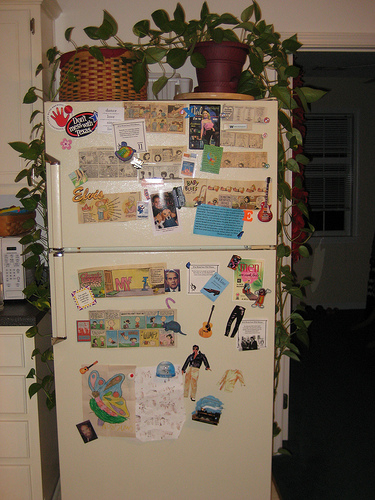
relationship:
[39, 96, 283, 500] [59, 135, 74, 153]
refrigerator covered with magnet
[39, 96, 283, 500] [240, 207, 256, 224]
refrigerator covered with magnet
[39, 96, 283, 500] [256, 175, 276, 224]
refrigerator covered with magnet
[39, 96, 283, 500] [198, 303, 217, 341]
refrigerator covered with magnet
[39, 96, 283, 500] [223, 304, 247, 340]
refrigerator covered with magnet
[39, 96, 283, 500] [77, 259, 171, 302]
refrigerator covered with comics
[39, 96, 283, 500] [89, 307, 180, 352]
refrigerator covered with comics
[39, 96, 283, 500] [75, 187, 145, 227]
refrigerator covered with comics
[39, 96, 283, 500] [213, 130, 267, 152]
refrigerator covered with comics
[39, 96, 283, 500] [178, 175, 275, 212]
refrigerator covered with comics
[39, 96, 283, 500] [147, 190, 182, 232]
refrigerator covered with photo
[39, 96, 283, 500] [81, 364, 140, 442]
refrigerator covered with artwork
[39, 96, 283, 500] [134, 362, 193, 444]
refrigerator covered with artwork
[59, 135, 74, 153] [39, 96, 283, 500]
magnet on refrigerator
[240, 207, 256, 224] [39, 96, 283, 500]
magnet on refrigerator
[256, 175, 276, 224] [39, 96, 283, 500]
magnet on refrigerator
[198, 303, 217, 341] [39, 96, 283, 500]
magnet on refrigerator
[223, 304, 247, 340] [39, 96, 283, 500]
magnet on refrigerator